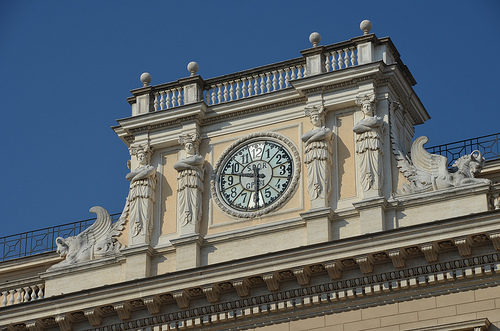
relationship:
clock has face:
[211, 132, 302, 218] [218, 138, 291, 208]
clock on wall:
[211, 132, 302, 218] [42, 83, 487, 301]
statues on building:
[88, 96, 495, 216] [3, 11, 499, 326]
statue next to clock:
[352, 100, 385, 200] [213, 134, 301, 213]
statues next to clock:
[300, 106, 333, 208] [213, 134, 301, 213]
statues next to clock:
[174, 132, 203, 234] [213, 134, 301, 213]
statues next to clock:
[126, 145, 155, 243] [213, 134, 301, 213]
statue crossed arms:
[351, 100, 385, 200] [352, 117, 402, 136]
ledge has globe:
[97, 13, 438, 142] [309, 32, 321, 44]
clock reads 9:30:
[211, 132, 302, 218] [221, 158, 283, 208]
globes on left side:
[129, 60, 244, 95] [97, 57, 255, 160]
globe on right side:
[359, 16, 374, 33] [289, 18, 438, 73]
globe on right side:
[309, 27, 322, 44] [289, 18, 438, 73]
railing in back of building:
[413, 128, 499, 167] [3, 11, 499, 326]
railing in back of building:
[3, 220, 100, 268] [3, 11, 499, 326]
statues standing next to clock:
[170, 128, 202, 229] [207, 131, 303, 216]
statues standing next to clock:
[126, 140, 150, 235] [207, 131, 303, 216]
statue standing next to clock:
[352, 100, 385, 200] [208, 118, 319, 243]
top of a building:
[69, 38, 483, 235] [3, 11, 499, 326]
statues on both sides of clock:
[300, 106, 333, 208] [207, 131, 303, 216]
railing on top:
[3, 220, 100, 268] [69, 38, 483, 235]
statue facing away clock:
[56, 205, 121, 260] [207, 131, 303, 216]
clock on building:
[206, 123, 311, 213] [27, 77, 484, 329]